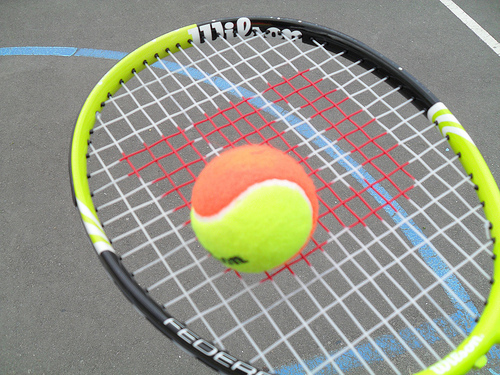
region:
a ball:
[154, 94, 279, 256]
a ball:
[192, 190, 332, 364]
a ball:
[227, 131, 352, 348]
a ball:
[220, 100, 324, 240]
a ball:
[114, 55, 264, 220]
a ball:
[164, 45, 332, 265]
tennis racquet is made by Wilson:
[156, 5, 368, 75]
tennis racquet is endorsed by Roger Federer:
[130, 298, 357, 373]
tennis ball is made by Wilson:
[174, 136, 329, 288]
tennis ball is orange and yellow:
[179, 140, 319, 283]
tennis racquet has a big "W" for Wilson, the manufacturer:
[99, 57, 431, 294]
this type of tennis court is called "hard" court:
[3, 4, 493, 137]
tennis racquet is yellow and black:
[61, 12, 497, 371]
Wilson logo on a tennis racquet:
[399, 321, 499, 373]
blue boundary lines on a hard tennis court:
[2, 25, 373, 133]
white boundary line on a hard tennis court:
[392, 0, 499, 57]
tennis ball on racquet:
[181, 142, 329, 280]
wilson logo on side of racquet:
[193, 10, 310, 45]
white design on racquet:
[68, 200, 113, 252]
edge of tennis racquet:
[435, 110, 472, 156]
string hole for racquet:
[452, 148, 467, 160]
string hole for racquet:
[463, 163, 476, 183]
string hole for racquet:
[479, 198, 485, 210]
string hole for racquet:
[487, 235, 495, 246]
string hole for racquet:
[406, 92, 419, 104]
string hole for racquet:
[378, 69, 391, 79]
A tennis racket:
[50, 16, 496, 357]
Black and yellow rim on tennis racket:
[70, 15, 491, 368]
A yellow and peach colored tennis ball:
[192, 150, 308, 265]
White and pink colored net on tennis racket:
[120, 80, 415, 255]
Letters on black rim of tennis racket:
[157, 311, 254, 371]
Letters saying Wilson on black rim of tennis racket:
[190, 11, 305, 46]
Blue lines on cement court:
[2, 36, 497, 367]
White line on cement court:
[438, 2, 498, 59]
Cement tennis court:
[6, 3, 499, 360]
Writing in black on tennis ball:
[211, 251, 251, 276]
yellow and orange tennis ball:
[178, 124, 327, 270]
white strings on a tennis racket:
[143, 28, 213, 113]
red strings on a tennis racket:
[151, 135, 198, 196]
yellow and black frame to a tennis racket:
[51, 68, 196, 371]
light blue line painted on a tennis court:
[8, 19, 100, 86]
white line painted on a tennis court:
[420, 3, 496, 53]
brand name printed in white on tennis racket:
[179, 12, 339, 59]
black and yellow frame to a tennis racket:
[263, 10, 498, 190]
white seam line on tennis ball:
[192, 173, 318, 234]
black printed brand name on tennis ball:
[211, 242, 259, 274]